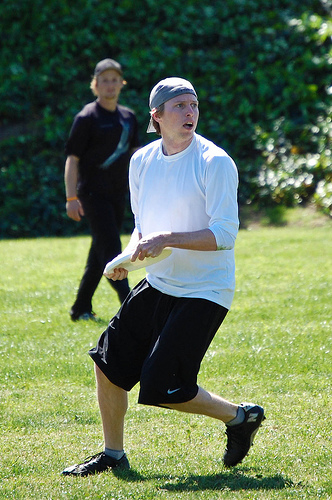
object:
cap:
[93, 58, 121, 78]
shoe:
[223, 399, 264, 467]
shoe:
[62, 451, 129, 477]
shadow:
[155, 475, 287, 494]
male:
[63, 77, 263, 480]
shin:
[162, 406, 240, 421]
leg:
[93, 281, 173, 449]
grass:
[1, 226, 330, 500]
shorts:
[89, 279, 229, 407]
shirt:
[104, 129, 239, 309]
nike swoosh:
[165, 385, 182, 395]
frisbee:
[104, 244, 173, 280]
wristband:
[68, 194, 78, 204]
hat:
[148, 74, 196, 134]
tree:
[0, 0, 331, 240]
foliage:
[0, 0, 332, 235]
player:
[64, 58, 137, 315]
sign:
[248, 412, 259, 424]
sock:
[229, 406, 248, 428]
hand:
[102, 268, 127, 281]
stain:
[217, 245, 233, 250]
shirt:
[66, 101, 139, 205]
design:
[99, 119, 133, 167]